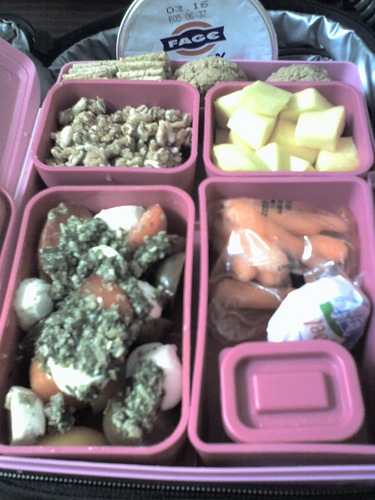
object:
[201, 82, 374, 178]
container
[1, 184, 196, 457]
container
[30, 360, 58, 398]
tomato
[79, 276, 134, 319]
tomato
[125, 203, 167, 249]
tomato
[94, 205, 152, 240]
mozzarella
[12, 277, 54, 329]
mozzarella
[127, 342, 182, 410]
mozzarella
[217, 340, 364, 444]
container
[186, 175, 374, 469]
container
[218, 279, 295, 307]
carrots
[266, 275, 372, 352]
cheese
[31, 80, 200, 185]
container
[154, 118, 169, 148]
walnuts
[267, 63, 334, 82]
cookies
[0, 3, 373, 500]
cooler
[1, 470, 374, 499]
zipper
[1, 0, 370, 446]
lunch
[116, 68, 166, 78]
crackers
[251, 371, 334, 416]
shape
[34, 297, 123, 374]
pesto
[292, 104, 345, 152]
apples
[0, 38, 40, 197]
lid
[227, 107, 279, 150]
pineapple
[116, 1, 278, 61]
yogurt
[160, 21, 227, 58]
label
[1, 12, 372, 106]
edge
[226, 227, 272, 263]
reflection